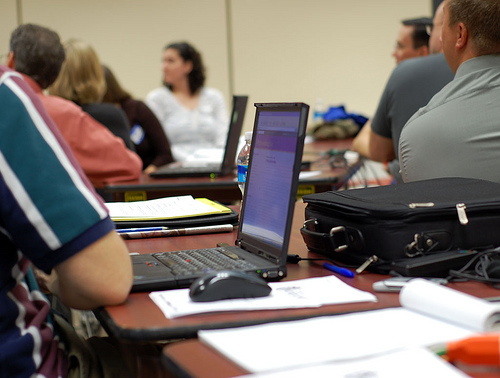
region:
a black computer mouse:
[184, 266, 276, 303]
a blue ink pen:
[320, 256, 357, 280]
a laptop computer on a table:
[135, 98, 307, 290]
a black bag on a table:
[295, 168, 497, 263]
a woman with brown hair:
[157, 32, 208, 89]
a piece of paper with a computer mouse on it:
[151, 266, 373, 323]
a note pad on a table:
[199, 287, 493, 376]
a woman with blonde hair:
[54, 37, 100, 102]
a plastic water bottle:
[310, 93, 327, 133]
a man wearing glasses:
[423, 12, 444, 34]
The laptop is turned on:
[237, 100, 307, 257]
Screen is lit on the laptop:
[238, 98, 298, 246]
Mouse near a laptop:
[176, 246, 274, 303]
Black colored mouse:
[171, 235, 272, 298]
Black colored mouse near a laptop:
[179, 247, 272, 299]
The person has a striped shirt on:
[4, 76, 96, 359]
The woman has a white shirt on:
[142, 26, 216, 117]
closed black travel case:
[295, 173, 498, 265]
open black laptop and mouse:
[127, 100, 308, 300]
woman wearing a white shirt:
[142, 40, 232, 149]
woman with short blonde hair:
[47, 35, 137, 151]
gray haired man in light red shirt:
[1, 21, 142, 181]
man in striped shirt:
[0, 62, 175, 376]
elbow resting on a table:
[57, 219, 154, 334]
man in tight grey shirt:
[397, 0, 498, 184]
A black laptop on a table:
[128, 96, 310, 294]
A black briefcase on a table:
[301, 168, 499, 280]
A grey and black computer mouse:
[188, 265, 270, 305]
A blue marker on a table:
[318, 259, 353, 276]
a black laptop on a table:
[146, 93, 249, 180]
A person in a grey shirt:
[393, 1, 498, 186]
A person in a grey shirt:
[366, 0, 456, 162]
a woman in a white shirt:
[144, 40, 231, 159]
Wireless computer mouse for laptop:
[186, 268, 275, 303]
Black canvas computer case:
[299, 178, 499, 280]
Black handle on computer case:
[298, 217, 353, 252]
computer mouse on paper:
[181, 270, 279, 302]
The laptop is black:
[128, 71, 348, 326]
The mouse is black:
[170, 241, 295, 335]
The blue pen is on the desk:
[288, 225, 401, 317]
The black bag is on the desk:
[260, 96, 499, 308]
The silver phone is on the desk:
[350, 250, 471, 314]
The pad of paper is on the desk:
[196, 263, 498, 375]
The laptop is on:
[125, 65, 390, 293]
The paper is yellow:
[62, 175, 289, 227]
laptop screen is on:
[240, 99, 300, 257]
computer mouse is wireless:
[190, 270, 274, 300]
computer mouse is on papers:
[146, 267, 385, 314]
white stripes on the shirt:
[0, 62, 109, 377]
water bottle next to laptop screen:
[233, 131, 256, 201]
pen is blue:
[318, 258, 359, 278]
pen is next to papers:
[315, 258, 355, 278]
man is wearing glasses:
[422, 19, 448, 35]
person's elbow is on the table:
[48, 218, 138, 317]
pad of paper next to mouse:
[194, 271, 498, 373]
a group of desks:
[72, 100, 494, 377]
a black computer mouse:
[178, 258, 284, 314]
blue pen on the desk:
[299, 249, 360, 279]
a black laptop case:
[291, 137, 498, 285]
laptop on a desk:
[84, 82, 327, 317]